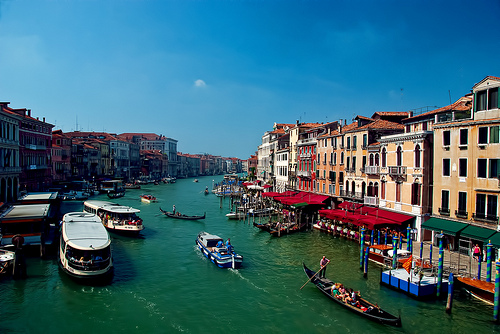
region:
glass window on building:
[443, 130, 453, 145]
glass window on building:
[458, 128, 468, 147]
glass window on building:
[477, 126, 487, 142]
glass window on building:
[486, 123, 496, 144]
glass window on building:
[441, 157, 450, 176]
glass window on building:
[458, 154, 468, 175]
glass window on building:
[476, 158, 486, 175]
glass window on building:
[440, 189, 449, 211]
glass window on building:
[488, 87, 498, 108]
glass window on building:
[478, 88, 488, 109]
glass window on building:
[443, 130, 451, 147]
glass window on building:
[458, 128, 468, 145]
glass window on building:
[477, 124, 487, 144]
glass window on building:
[488, 125, 498, 142]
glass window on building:
[488, 155, 497, 177]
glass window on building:
[476, 159, 486, 179]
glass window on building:
[474, 89, 486, 111]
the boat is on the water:
[60, 209, 109, 276]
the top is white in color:
[62, 205, 103, 250]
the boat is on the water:
[196, 230, 233, 265]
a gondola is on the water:
[157, 202, 209, 222]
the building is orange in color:
[380, 130, 426, 215]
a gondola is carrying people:
[292, 251, 397, 326]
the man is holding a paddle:
[297, 252, 331, 293]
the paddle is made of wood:
[299, 260, 329, 294]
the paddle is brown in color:
[297, 263, 325, 293]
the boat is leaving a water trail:
[227, 262, 262, 293]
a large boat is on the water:
[59, 210, 114, 280]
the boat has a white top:
[84, 195, 140, 215]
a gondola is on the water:
[296, 251, 399, 328]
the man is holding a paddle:
[297, 261, 329, 295]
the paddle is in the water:
[300, 263, 326, 298]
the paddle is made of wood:
[298, 267, 325, 292]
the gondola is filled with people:
[300, 250, 402, 329]